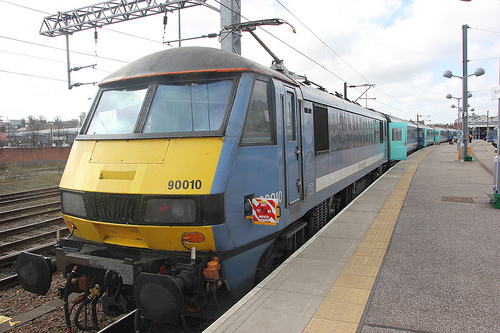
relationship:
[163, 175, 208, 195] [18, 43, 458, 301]
numbers on train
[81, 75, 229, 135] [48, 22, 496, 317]
windshield on train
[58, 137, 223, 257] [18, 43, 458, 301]
yellow section of train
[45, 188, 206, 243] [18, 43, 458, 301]
lights on train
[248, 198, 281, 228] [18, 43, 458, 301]
sign on train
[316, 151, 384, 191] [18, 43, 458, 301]
stripe on train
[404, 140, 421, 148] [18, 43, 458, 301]
stripe on train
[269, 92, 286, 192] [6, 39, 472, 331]
door on train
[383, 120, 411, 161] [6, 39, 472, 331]
door open on train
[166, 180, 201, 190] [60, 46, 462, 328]
black number on train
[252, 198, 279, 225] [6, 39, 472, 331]
sign on train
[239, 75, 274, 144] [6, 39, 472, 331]
window on train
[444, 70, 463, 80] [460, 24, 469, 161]
light on gray pole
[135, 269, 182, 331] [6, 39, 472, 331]
bumper on train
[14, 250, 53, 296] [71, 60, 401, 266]
bumper on train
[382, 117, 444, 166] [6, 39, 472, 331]
doors train on train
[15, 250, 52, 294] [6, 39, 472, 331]
bumper on train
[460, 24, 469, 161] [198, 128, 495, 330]
gray pole on platform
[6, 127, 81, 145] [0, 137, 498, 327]
houses behind train station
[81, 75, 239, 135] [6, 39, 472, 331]
windshield on train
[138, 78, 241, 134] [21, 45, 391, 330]
front windshield on front of train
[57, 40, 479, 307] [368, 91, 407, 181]
train has door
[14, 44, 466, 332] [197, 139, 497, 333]
train stopping at train station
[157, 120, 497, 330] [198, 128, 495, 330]
train station has platform